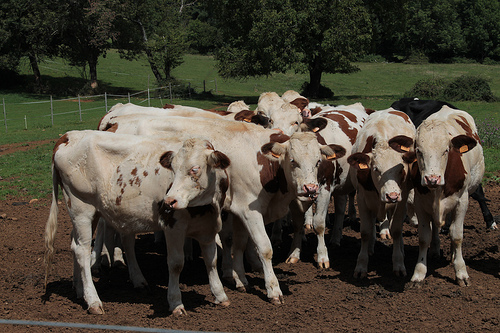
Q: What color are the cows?
A: White and brown.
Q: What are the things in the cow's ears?
A: Tags.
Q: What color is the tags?
A: Yellow.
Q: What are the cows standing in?
A: Mud.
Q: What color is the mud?
A: Brown.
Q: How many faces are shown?
A: Four.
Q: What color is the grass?
A: Green.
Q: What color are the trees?
A: Green.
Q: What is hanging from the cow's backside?
A: Tail.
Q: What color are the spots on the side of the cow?
A: Brown.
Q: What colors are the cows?
A: Brown and white.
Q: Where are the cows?
A: Outside in a pasture.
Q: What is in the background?
A: Trees.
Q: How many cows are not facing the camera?
A: One.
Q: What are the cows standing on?
A: Dirt.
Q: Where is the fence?
A: In the distance to the left.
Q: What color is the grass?
A: Green.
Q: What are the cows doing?
A: Standing.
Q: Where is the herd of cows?
A: In the pasture.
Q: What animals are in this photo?
A: Calves.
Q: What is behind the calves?
A: Trees and grass.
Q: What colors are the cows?
A: White.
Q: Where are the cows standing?
A: In a field.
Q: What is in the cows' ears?
A: Tags.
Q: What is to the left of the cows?
A: A fence.